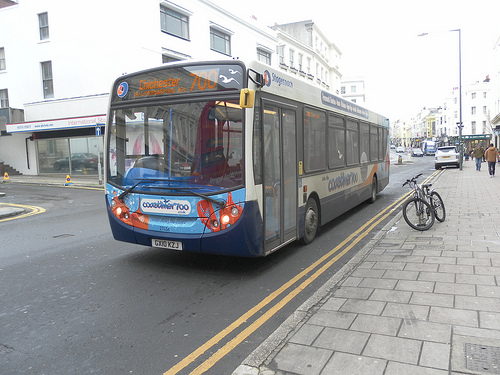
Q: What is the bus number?
A: 700.